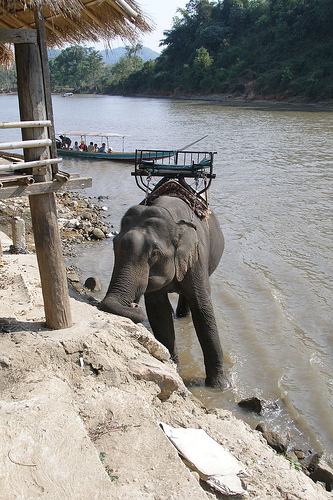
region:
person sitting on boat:
[98, 143, 107, 151]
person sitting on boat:
[105, 145, 114, 153]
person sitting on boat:
[92, 142, 99, 153]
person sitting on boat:
[85, 142, 96, 151]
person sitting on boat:
[76, 138, 87, 152]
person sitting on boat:
[71, 140, 80, 150]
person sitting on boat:
[57, 133, 69, 149]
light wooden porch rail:
[2, 117, 51, 132]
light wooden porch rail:
[2, 134, 50, 156]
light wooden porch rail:
[0, 158, 63, 176]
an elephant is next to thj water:
[93, 165, 227, 408]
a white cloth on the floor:
[175, 414, 261, 498]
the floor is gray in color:
[73, 358, 170, 498]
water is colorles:
[263, 263, 330, 359]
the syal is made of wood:
[11, 88, 103, 341]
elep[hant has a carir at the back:
[134, 135, 242, 302]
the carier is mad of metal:
[147, 135, 216, 186]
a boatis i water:
[67, 107, 143, 195]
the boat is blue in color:
[66, 113, 132, 160]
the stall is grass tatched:
[33, 3, 172, 49]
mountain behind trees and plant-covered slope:
[5, 2, 325, 96]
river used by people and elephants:
[1, 85, 326, 456]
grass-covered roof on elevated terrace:
[3, 0, 146, 329]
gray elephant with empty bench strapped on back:
[93, 144, 226, 402]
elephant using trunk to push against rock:
[77, 201, 176, 358]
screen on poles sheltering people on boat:
[52, 127, 208, 158]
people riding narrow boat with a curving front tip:
[51, 126, 208, 162]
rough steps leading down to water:
[0, 329, 324, 493]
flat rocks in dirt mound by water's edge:
[0, 186, 112, 242]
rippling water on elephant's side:
[104, 222, 328, 465]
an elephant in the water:
[96, 142, 252, 396]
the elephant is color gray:
[97, 177, 239, 400]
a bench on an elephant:
[125, 141, 221, 225]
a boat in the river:
[55, 122, 215, 168]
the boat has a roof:
[56, 124, 135, 157]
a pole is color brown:
[6, 15, 77, 338]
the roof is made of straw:
[0, 5, 156, 142]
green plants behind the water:
[1, 5, 328, 114]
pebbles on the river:
[59, 189, 114, 248]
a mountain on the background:
[47, 37, 164, 80]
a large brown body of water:
[1, 92, 332, 469]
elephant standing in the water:
[99, 179, 230, 397]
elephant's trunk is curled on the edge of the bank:
[93, 232, 151, 339]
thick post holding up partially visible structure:
[0, 5, 157, 331]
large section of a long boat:
[51, 130, 206, 158]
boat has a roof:
[53, 128, 120, 150]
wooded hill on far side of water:
[78, 0, 328, 117]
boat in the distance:
[59, 89, 70, 94]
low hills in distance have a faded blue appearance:
[47, 44, 161, 68]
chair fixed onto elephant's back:
[131, 148, 217, 227]